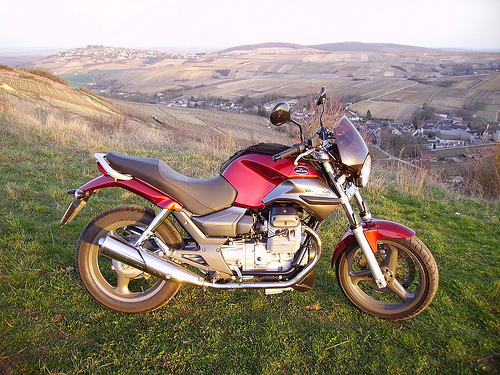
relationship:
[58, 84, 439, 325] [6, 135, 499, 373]
motorcycle on hill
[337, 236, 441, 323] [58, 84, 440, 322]
tire of motorcycle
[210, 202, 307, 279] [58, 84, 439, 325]
engine of motorcycle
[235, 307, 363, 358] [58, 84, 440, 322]
grass beside motorcycle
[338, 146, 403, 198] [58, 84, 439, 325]
light on motorcycle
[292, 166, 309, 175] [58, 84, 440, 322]
label on motorcycle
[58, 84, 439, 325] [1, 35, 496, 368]
motorcycle on grass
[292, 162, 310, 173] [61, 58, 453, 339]
label on motorcycle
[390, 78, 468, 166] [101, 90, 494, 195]
buildings in valley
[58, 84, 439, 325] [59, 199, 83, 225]
motorcycle has plate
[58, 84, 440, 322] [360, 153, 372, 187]
motorcycle has light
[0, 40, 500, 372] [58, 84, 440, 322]
valley on motorcycle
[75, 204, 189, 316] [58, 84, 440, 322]
wheel on motorcycle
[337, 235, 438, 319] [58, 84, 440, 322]
wheel on motorcycle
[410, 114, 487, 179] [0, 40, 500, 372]
buildings in valley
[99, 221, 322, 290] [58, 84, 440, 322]
exhaust pipe on motorcycle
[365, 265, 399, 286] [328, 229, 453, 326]
spokes on wheels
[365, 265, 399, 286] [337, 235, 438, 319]
spokes on wheel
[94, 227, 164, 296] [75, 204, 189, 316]
spokes on wheel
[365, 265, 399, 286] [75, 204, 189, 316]
spokes on wheel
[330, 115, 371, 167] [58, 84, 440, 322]
farrings on motorcycle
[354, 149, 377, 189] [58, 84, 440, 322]
headlight on motorcycle